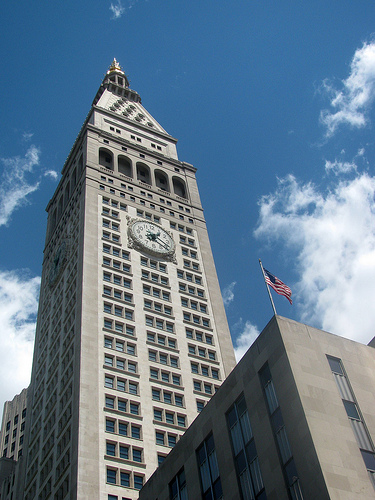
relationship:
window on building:
[124, 357, 140, 374] [21, 50, 236, 496]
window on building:
[101, 437, 119, 460] [21, 50, 236, 496]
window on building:
[101, 370, 114, 389] [21, 50, 236, 496]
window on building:
[130, 422, 144, 441] [21, 50, 236, 496]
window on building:
[151, 385, 164, 404] [21, 50, 236, 496]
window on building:
[121, 322, 139, 340] [35, 55, 254, 403]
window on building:
[102, 196, 111, 205] [21, 50, 236, 496]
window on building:
[104, 336, 113, 347] [21, 50, 236, 496]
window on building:
[102, 220, 110, 228] [21, 50, 236, 496]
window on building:
[144, 283, 148, 293] [21, 50, 236, 496]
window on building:
[179, 296, 188, 305] [21, 50, 236, 496]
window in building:
[103, 334, 114, 348] [2, 57, 374, 498]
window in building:
[116, 337, 124, 354] [2, 57, 374, 498]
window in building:
[127, 342, 135, 353] [2, 57, 374, 498]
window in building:
[148, 348, 157, 361] [2, 57, 374, 498]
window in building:
[158, 353, 168, 364] [2, 57, 374, 498]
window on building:
[102, 218, 111, 234] [40, 41, 243, 426]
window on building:
[100, 144, 115, 177] [24, 39, 367, 495]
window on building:
[113, 301, 124, 316] [21, 50, 236, 496]